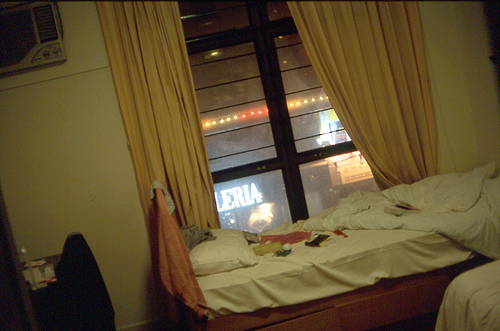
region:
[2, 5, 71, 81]
air conditioner on the wall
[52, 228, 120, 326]
coat hanging on the chair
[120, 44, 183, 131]
curtain on the window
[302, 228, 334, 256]
book on the bed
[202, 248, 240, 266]
white pillow on the bed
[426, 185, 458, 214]
white sheet on the bed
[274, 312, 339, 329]
drawer under the bed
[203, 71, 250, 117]
lines on the window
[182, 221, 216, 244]
gray shirt on the pillow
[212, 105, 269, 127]
lights outside the window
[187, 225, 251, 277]
the white pillow on the bed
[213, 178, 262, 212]
the bright blue neon sign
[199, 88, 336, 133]
the line of bright lights outside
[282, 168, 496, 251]
the messy blanket on the bed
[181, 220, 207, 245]
the grey shirt on the pillow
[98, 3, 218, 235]
the yellow curtain on the wall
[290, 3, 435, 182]
the yellow curtain on the wall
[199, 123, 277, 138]
the black bar on the window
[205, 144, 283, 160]
the black bar on the window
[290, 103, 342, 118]
the black bar on the window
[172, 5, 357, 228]
black frame on window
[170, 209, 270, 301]
white pillow on bed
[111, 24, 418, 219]
yellow curtains around window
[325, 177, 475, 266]
white blanket on bed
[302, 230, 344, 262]
black book on bed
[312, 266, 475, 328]
brown frame under bed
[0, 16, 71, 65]
air conditioner near curtain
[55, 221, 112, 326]
coat is on chair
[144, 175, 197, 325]
towel on head of bed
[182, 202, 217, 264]
shirt is on pillow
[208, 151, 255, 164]
Small bar on the window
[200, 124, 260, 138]
Small bar on the window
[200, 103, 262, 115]
Small bar on the window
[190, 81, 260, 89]
Small bar on the window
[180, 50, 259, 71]
Small bar on the window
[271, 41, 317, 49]
Small bar on the window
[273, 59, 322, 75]
Small bar on the window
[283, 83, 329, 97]
Small bar on the window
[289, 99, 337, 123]
Small bar on the window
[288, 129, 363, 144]
Small bar on the window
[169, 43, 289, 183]
this is a window pane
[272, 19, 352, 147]
this is a window pane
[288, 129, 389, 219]
this is a window pane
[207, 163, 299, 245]
this is a window pane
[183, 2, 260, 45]
this is a window pane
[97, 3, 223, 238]
this is a curtain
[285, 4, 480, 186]
this is a curtain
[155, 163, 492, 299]
this is a bed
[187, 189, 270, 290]
this is a pillow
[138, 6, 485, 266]
this is a window